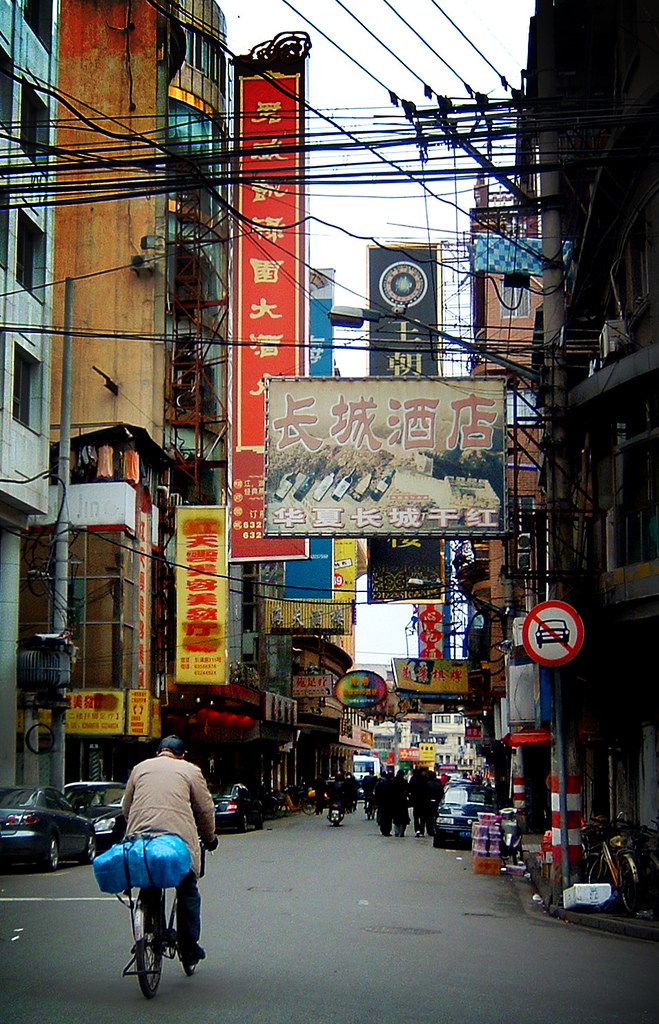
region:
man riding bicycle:
[106, 723, 248, 962]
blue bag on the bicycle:
[92, 831, 192, 891]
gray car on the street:
[6, 774, 97, 875]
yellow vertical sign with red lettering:
[179, 497, 228, 685]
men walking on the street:
[359, 753, 441, 837]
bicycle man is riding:
[111, 861, 220, 996]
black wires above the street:
[9, 3, 559, 620]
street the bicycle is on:
[1, 740, 624, 1022]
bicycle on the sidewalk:
[572, 817, 645, 920]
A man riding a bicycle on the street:
[150, 735, 195, 962]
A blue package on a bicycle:
[116, 849, 173, 881]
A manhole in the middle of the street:
[377, 924, 424, 932]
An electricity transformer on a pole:
[16, 648, 68, 683]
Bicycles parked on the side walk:
[598, 836, 646, 878]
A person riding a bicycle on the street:
[328, 772, 346, 825]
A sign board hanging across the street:
[272, 448, 487, 532]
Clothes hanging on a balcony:
[92, 445, 137, 478]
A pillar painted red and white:
[568, 799, 581, 845]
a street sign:
[529, 604, 580, 908]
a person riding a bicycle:
[111, 735, 203, 984]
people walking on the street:
[284, 754, 450, 826]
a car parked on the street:
[5, 780, 98, 862]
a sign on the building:
[293, 674, 336, 694]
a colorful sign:
[337, 666, 379, 702]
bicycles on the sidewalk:
[582, 819, 654, 903]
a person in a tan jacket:
[125, 743, 199, 839]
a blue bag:
[91, 837, 177, 885]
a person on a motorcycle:
[326, 774, 347, 824]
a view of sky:
[325, 55, 368, 107]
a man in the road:
[88, 723, 271, 992]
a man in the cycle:
[91, 732, 247, 1007]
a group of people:
[326, 739, 448, 860]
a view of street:
[132, 713, 493, 903]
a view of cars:
[39, 761, 140, 893]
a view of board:
[498, 579, 617, 686]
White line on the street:
[17, 888, 101, 910]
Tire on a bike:
[127, 894, 175, 999]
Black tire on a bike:
[124, 888, 177, 1003]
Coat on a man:
[115, 751, 220, 869]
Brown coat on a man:
[108, 747, 231, 875]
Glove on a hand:
[204, 831, 223, 857]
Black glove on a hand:
[203, 835, 221, 852]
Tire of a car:
[41, 835, 63, 875]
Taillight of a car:
[2, 809, 43, 828]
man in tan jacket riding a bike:
[104, 732, 220, 990]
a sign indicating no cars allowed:
[520, 598, 582, 662]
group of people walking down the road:
[374, 762, 438, 838]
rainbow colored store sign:
[336, 671, 385, 705]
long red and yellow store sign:
[176, 507, 225, 678]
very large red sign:
[233, 58, 267, 556]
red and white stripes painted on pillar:
[510, 772, 527, 817]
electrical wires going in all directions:
[1, 70, 555, 212]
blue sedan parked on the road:
[1, 769, 91, 865]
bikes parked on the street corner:
[583, 811, 648, 919]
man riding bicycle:
[103, 728, 230, 891]